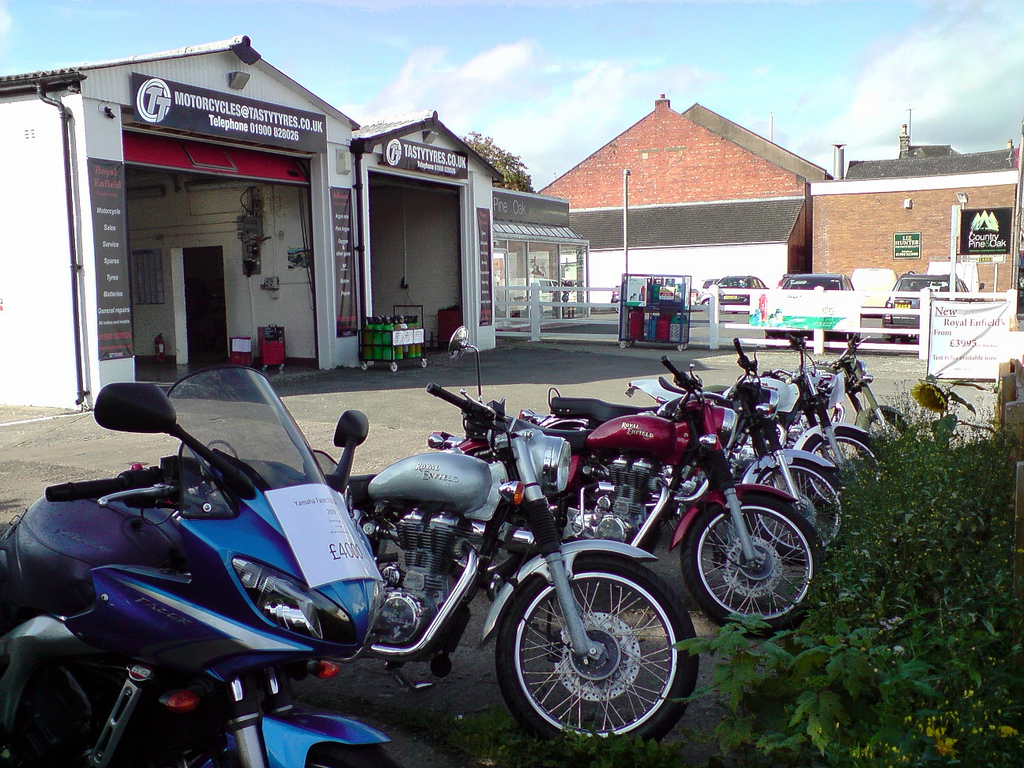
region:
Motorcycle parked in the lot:
[790, 319, 890, 444]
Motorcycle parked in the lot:
[751, 313, 872, 478]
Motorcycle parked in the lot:
[540, 338, 829, 639]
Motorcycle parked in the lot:
[366, 344, 696, 706]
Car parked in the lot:
[759, 259, 857, 346]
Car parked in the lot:
[879, 262, 969, 336]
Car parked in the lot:
[698, 269, 771, 327]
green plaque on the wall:
[893, 230, 925, 259]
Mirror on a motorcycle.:
[85, 383, 257, 502]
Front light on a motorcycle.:
[228, 540, 365, 664]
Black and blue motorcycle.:
[10, 345, 426, 754]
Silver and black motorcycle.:
[309, 379, 702, 756]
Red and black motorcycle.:
[476, 379, 824, 633]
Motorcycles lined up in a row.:
[313, 322, 902, 766]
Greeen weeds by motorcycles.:
[778, 392, 1022, 753]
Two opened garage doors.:
[24, 38, 509, 394]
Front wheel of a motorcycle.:
[489, 532, 695, 741]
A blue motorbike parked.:
[1, 364, 400, 766]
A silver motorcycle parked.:
[332, 380, 699, 751]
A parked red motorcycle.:
[425, 353, 822, 633]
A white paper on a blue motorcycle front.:
[264, 487, 386, 589]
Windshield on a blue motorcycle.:
[166, 364, 329, 497]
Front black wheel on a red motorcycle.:
[680, 485, 824, 635]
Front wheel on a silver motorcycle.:
[494, 555, 701, 755]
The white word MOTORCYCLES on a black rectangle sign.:
[168, 87, 244, 119]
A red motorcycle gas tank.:
[588, 409, 677, 457]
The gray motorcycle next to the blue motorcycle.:
[294, 382, 688, 746]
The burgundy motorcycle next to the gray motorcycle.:
[457, 366, 822, 633]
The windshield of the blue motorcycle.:
[154, 361, 335, 543]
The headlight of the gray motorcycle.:
[527, 434, 567, 496]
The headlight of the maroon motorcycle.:
[720, 408, 743, 440]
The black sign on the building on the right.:
[954, 203, 1011, 249]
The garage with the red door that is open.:
[128, 133, 325, 368]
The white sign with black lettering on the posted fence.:
[931, 291, 1007, 383]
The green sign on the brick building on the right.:
[896, 233, 919, 259]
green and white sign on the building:
[883, 231, 925, 266]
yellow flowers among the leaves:
[886, 696, 1017, 764]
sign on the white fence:
[756, 284, 865, 339]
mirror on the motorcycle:
[89, 377, 172, 447]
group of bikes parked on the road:
[36, 360, 808, 749]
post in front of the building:
[611, 165, 635, 277]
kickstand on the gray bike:
[387, 669, 430, 701]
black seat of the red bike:
[555, 418, 590, 451]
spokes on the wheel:
[592, 620, 640, 652]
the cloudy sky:
[6, 0, 1021, 182]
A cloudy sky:
[8, 4, 1020, 200]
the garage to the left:
[8, 36, 348, 390]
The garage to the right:
[340, 101, 514, 352]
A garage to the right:
[355, 121, 533, 377]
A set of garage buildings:
[10, 5, 513, 357]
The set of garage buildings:
[11, 21, 509, 389]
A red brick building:
[528, 62, 1012, 319]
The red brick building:
[526, 85, 1021, 320]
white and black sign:
[130, 74, 324, 144]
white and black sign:
[377, 135, 464, 175]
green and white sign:
[965, 208, 1011, 254]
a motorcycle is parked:
[0, 381, 412, 767]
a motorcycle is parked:
[342, 375, 694, 753]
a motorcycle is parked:
[460, 362, 816, 639]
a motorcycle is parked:
[757, 325, 882, 494]